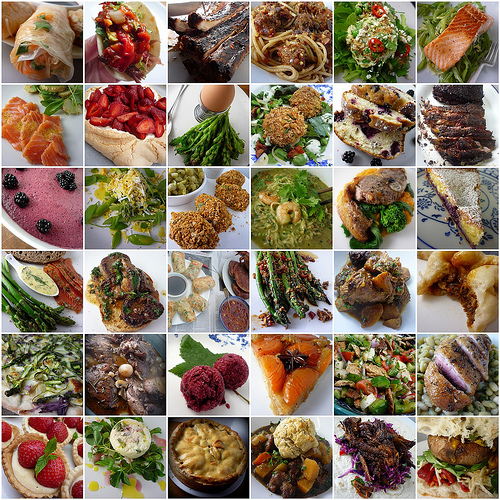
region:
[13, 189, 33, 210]
a raspberry on top of a dessert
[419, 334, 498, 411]
a sliced chicken breast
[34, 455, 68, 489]
a strawberry on top of a tart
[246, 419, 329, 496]
a bowl of beef stew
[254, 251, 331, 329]
a dish of asparagus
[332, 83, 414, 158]
slices of blackberry bread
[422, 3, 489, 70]
a slice of fish on greens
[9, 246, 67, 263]
a piece of brown bread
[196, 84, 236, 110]
a brown egg in an egg cup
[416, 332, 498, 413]
rice under a chicken breast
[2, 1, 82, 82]
a spring roll with greens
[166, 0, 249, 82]
a small picture of meat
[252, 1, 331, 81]
meat and noodles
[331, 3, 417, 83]
greens and some sort of slaw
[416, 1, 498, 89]
fish on green noodles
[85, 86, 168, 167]
fresh fruit and pastry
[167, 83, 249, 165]
asparagus and an egg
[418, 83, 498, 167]
a plate of meat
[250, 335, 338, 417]
a fruit pie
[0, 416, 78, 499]
desert with fresh strawberries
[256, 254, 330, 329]
asparagus on white plate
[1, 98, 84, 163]
fresh salmon on white plate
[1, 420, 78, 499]
red strawberries on pastries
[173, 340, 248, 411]
red berries on plate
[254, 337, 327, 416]
orange peaches on plate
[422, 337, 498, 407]
meat on garnish on plate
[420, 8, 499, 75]
piece of cooked fish on plate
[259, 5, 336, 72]
spaghetti and meatballs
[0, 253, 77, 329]
asparagus near white spoon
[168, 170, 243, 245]
small breaded objects on plate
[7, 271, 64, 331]
this is a green vegetable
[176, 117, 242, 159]
this is a green vegetable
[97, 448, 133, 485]
this is a green vegetable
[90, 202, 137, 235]
this is a green vegetable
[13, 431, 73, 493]
this is a red strawberry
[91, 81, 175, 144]
this is red in colour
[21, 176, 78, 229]
this is pink in colour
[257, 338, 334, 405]
this is orange in colour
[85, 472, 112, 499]
this is yellow in colour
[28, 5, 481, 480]
these are types of food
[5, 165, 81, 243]
THIS IS A CAKE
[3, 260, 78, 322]
THESE ARE GREEN VEGATABLES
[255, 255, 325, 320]
THESE ARE GREEN VEGATABLES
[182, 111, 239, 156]
THESE AR GREEN VEGATABLES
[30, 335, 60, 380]
THESE ARE GREEN VEGATABLES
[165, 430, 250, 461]
THESE ARE WHITE MUSHROOMS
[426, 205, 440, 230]
THIS IS A PLATE OF GLASS